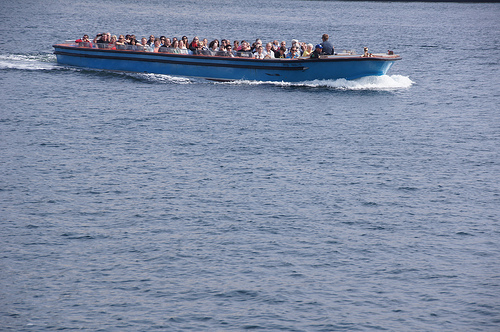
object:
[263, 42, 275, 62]
people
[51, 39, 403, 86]
boat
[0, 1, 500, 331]
water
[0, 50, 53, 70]
waves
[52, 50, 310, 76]
line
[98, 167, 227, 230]
ripple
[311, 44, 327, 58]
person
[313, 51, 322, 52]
hat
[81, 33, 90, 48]
person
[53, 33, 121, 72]
back of boat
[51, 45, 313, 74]
shield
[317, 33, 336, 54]
man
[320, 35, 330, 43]
head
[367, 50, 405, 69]
bow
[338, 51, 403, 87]
front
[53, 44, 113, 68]
back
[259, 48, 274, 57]
shirt